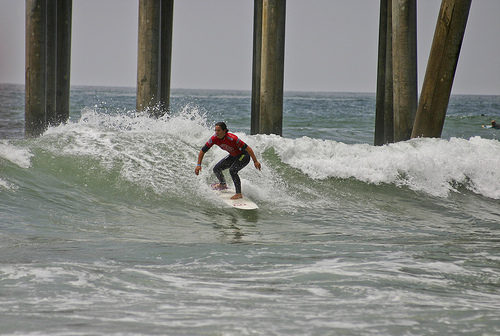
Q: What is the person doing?
A: Surfing.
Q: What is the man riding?
A: Surfboard.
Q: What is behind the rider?
A: A wave.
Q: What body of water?
A: Ocean.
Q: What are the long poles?
A: Support for pier.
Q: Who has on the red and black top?
A: A lady.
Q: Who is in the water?
A: A lady.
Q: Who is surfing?
A: A woman.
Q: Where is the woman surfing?
A: Next to a pier.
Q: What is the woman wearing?
A: A bodysuit.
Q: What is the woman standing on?
A: A surfboard.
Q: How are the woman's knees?
A: Bent.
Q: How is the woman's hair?
A: Wet.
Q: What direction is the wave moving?
A: To the right.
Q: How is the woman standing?
A: Bent down.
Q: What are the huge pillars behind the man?
A: They are holding up the pier.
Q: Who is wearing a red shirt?
A: The surfer.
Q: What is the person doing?
A: Surfing.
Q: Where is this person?
A: In the ocean.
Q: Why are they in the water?
A: Surfing.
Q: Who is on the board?
A: The surfer.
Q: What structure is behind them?
A: Dock.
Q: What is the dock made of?
A: Wood.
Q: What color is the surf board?
A: White.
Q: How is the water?
A: Wavy.